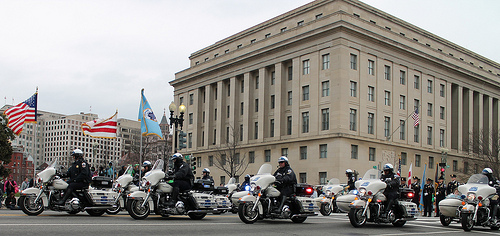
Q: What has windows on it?
A: The building.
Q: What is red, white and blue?
A: Flag.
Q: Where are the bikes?
A: On the street.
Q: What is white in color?
A: The helmets.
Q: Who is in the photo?
A: Police.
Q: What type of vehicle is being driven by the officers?
A: Motorcycle.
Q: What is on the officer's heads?
A: Helmets.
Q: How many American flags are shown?
A: One.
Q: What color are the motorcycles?
A: White.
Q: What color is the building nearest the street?
A: Tan.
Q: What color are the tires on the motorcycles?
A: Black.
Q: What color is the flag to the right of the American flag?
A: Red and white.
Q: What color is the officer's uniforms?
A: Black.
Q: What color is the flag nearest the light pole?
A: Blue.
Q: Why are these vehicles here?
A: It's a parade.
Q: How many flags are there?
A: Three.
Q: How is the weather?
A: Cloudy.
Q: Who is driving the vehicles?
A: Policemen.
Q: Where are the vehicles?
A: In an intersection.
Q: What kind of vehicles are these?
A: Motorcycles.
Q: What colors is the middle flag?
A: Red and white.